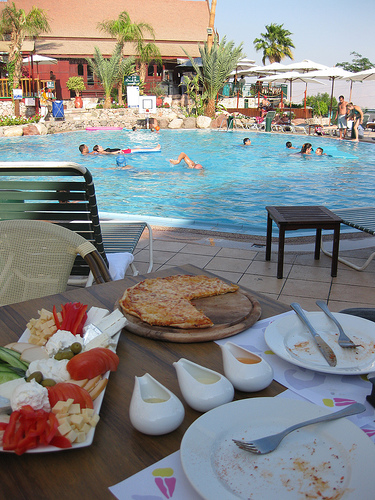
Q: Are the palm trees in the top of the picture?
A: Yes, the palm trees are in the top of the image.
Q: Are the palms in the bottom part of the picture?
A: No, the palms are in the top of the image.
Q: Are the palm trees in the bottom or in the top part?
A: The palm trees are in the top of the image.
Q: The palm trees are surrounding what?
A: The palm trees are surrounding the pool.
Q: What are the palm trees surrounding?
A: The palm trees are surrounding the pool.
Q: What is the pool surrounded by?
A: The pool is surrounded by the palm trees.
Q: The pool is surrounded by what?
A: The pool is surrounded by the palm trees.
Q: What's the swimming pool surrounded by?
A: The pool is surrounded by the palm trees.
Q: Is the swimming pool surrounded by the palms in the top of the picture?
A: Yes, the swimming pool is surrounded by the palm trees.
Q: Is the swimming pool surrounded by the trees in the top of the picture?
A: Yes, the swimming pool is surrounded by the palm trees.